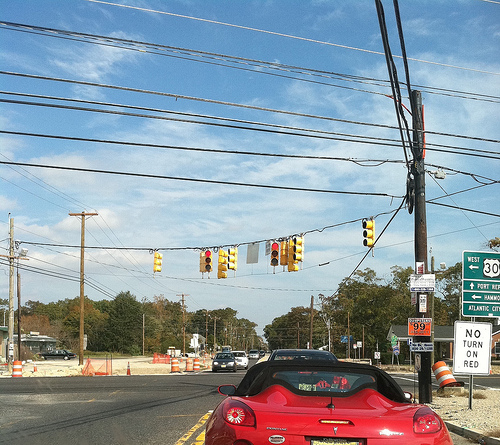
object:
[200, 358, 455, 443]
car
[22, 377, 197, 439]
road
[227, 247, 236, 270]
traffic light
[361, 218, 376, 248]
traffic light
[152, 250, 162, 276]
traffic light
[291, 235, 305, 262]
traffic light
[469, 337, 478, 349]
letter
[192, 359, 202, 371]
cone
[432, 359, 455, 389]
cone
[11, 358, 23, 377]
cone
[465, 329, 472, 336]
black letter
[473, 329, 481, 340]
black letter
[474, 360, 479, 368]
black letter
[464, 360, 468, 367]
black letter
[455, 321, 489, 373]
sign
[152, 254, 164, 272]
color yellow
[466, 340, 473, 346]
letter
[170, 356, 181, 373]
cone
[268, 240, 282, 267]
light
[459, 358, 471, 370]
letter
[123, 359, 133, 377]
orange cone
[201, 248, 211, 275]
traffic light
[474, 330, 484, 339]
letter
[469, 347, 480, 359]
letter